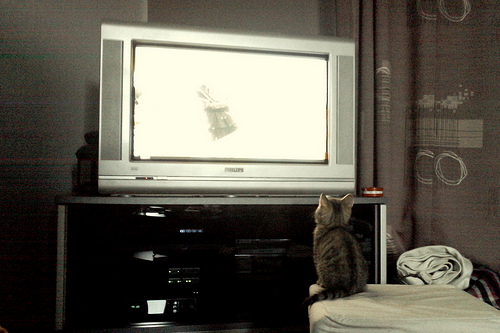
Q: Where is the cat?
A: On the edge of the bed.